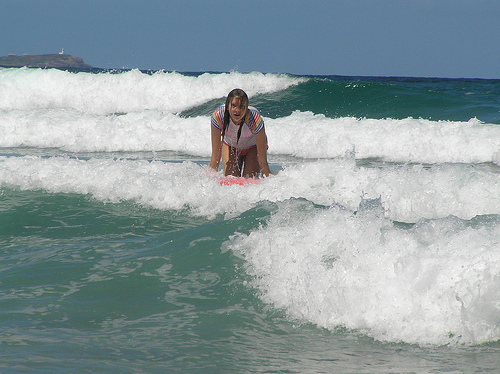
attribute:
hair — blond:
[226, 99, 263, 153]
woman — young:
[201, 87, 280, 184]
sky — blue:
[263, 4, 415, 94]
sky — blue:
[266, 3, 340, 53]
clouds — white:
[159, 8, 311, 91]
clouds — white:
[225, 1, 339, 59]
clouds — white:
[239, 1, 388, 91]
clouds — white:
[192, 4, 402, 84]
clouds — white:
[148, 1, 335, 71]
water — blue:
[263, 68, 499, 331]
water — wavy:
[5, 164, 288, 331]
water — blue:
[59, 217, 371, 367]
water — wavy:
[17, 168, 438, 371]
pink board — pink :
[207, 163, 283, 188]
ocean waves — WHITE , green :
[346, 237, 410, 305]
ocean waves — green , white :
[419, 196, 466, 247]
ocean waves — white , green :
[114, 273, 251, 335]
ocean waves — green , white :
[248, 275, 338, 356]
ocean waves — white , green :
[60, 221, 133, 291]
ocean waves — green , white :
[100, 100, 190, 184]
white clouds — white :
[305, 8, 360, 66]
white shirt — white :
[210, 107, 264, 152]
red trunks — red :
[225, 141, 263, 155]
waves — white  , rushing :
[0, 68, 498, 340]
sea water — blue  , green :
[1, 60, 498, 370]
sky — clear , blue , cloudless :
[3, 0, 498, 70]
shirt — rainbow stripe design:
[198, 95, 271, 160]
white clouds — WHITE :
[25, 10, 79, 43]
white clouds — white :
[57, 16, 103, 73]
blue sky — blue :
[6, 0, 497, 61]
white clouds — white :
[164, 19, 195, 49]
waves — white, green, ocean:
[291, 122, 355, 234]